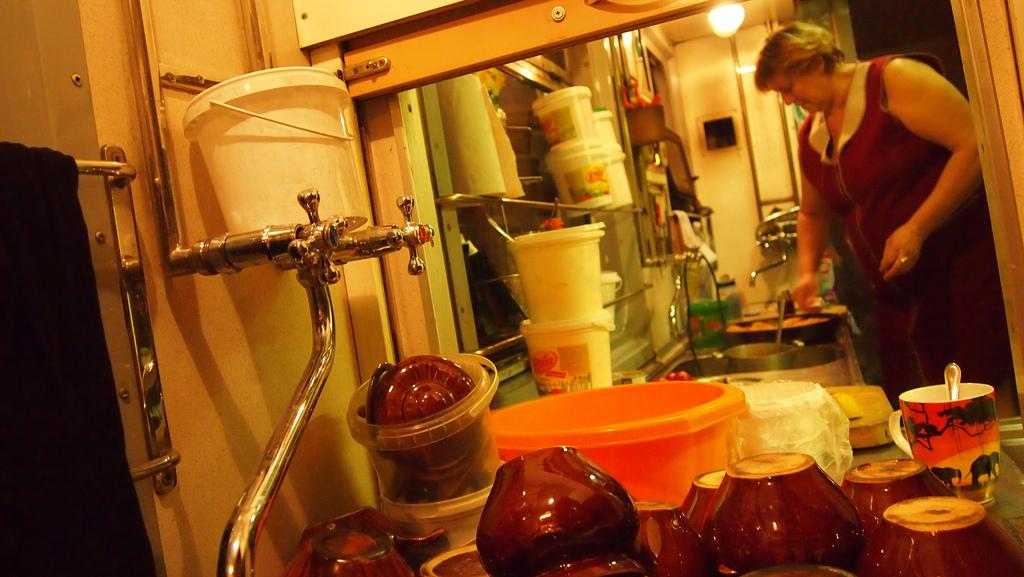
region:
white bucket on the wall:
[177, 64, 373, 226]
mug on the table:
[880, 366, 1004, 493]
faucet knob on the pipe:
[305, 192, 436, 287]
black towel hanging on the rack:
[2, 138, 105, 562]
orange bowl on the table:
[501, 375, 754, 473]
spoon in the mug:
[923, 342, 987, 425]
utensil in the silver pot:
[768, 278, 792, 345]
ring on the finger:
[892, 244, 911, 271]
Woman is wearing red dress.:
[748, 45, 995, 393]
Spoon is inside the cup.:
[882, 352, 1013, 501]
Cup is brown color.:
[465, 459, 981, 576]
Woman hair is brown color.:
[747, 26, 847, 83]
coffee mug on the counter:
[893, 364, 1012, 495]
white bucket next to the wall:
[162, 62, 368, 225]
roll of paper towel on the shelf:
[438, 81, 516, 206]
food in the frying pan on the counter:
[731, 312, 836, 344]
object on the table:
[721, 474, 870, 572]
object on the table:
[858, 458, 913, 479]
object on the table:
[484, 319, 608, 380]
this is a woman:
[735, 13, 999, 399]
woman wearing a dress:
[741, 17, 1020, 397]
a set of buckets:
[433, 42, 683, 397]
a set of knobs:
[223, 177, 449, 282]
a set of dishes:
[458, 402, 993, 573]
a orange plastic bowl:
[463, 358, 764, 555]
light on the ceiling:
[681, 0, 768, 55]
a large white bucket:
[140, 48, 398, 251]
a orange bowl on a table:
[481, 353, 748, 503]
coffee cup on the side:
[865, 370, 1006, 484]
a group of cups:
[429, 405, 996, 567]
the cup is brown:
[440, 451, 653, 573]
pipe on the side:
[129, 240, 373, 573]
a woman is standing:
[726, 2, 1022, 376]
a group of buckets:
[455, 35, 672, 393]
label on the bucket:
[516, 323, 596, 399]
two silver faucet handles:
[283, 189, 438, 281]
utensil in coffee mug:
[890, 356, 998, 500]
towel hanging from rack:
[0, 139, 180, 574]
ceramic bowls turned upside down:
[481, 448, 1010, 575]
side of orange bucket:
[485, 382, 748, 510]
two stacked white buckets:
[510, 220, 616, 389]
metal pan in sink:
[677, 340, 837, 383]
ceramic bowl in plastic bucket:
[346, 351, 502, 503]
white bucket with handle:
[184, 68, 371, 236]